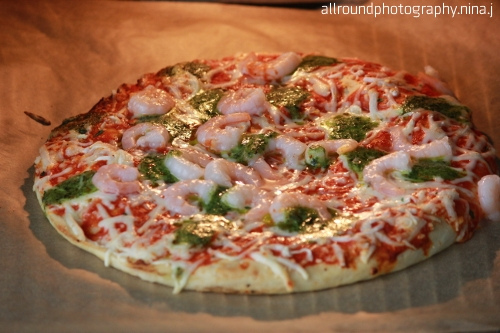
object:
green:
[351, 152, 371, 163]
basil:
[360, 151, 411, 197]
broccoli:
[320, 107, 375, 141]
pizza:
[32, 51, 500, 297]